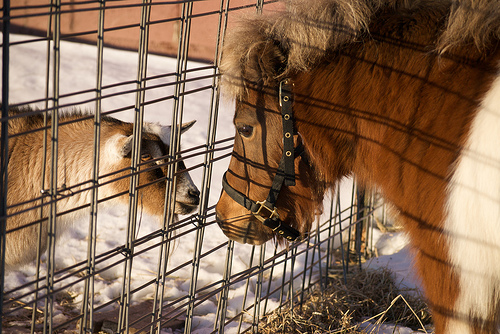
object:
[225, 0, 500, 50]
mane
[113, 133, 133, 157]
ear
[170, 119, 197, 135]
ear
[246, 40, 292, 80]
ear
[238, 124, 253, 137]
eye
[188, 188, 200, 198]
nose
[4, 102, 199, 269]
animal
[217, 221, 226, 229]
nostril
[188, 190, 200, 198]
nostril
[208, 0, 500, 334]
pony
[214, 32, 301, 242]
harness